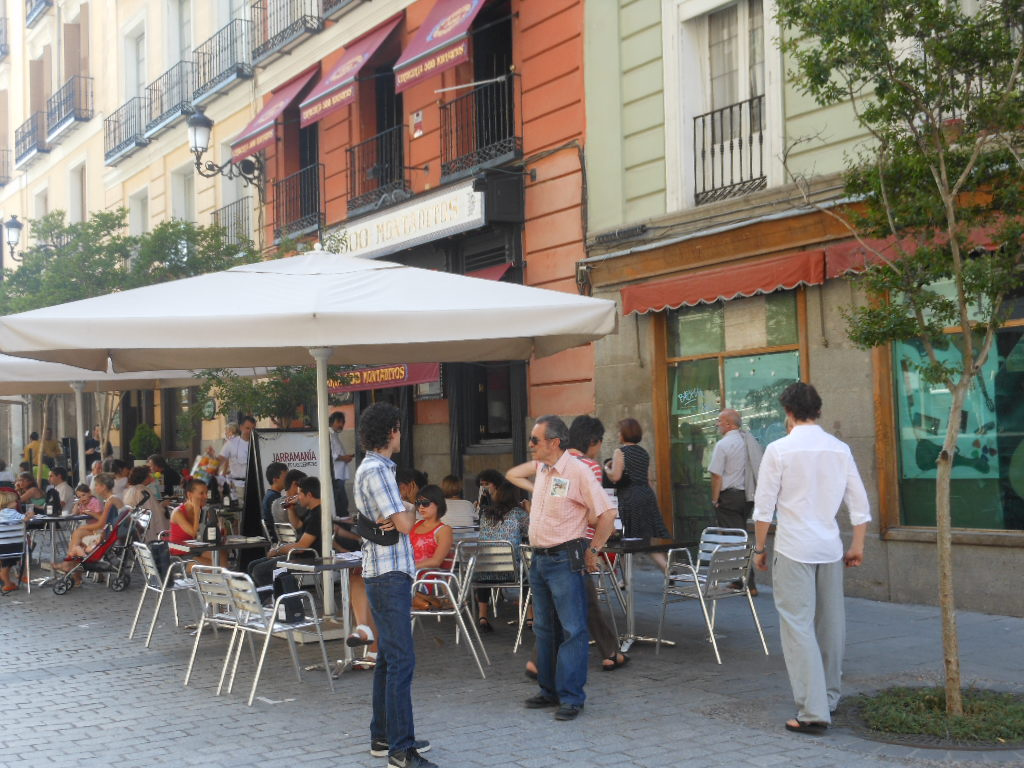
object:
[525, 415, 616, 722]
man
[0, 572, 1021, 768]
ground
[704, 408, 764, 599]
person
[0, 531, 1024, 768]
sidewalk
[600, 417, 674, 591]
person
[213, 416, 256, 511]
person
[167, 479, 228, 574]
person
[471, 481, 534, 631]
person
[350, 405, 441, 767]
man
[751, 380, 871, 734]
man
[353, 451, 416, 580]
shirt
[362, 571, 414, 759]
blue jeans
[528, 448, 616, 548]
shirt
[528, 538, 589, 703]
blue jeans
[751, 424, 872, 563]
shirt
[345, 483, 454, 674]
woman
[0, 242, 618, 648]
umbrella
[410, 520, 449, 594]
dress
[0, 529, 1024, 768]
street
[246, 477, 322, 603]
man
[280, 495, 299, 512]
glass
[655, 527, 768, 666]
chair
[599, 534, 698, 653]
table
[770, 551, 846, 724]
pants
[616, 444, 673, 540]
dress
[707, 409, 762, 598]
man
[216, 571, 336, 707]
chair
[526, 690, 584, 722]
shoes